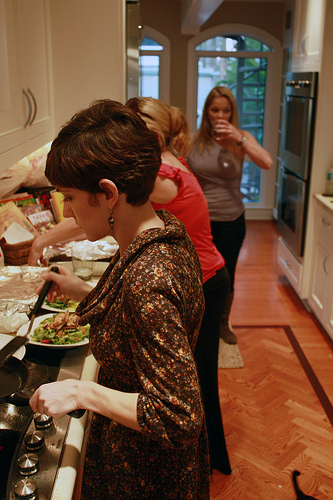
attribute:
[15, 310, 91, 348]
plate — full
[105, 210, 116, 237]
earring — dangling